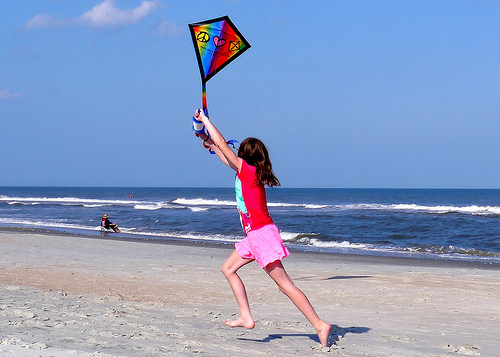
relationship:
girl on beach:
[193, 108, 338, 347] [1, 230, 499, 355]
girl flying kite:
[193, 108, 338, 347] [187, 16, 253, 115]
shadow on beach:
[238, 320, 372, 348] [1, 230, 499, 355]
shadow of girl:
[238, 320, 372, 348] [193, 108, 338, 347]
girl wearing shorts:
[193, 108, 338, 347] [233, 225, 292, 270]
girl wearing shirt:
[193, 108, 338, 347] [234, 156, 275, 234]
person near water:
[101, 213, 121, 234] [1, 186, 499, 259]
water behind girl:
[1, 186, 499, 259] [193, 108, 338, 347]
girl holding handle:
[193, 108, 338, 347] [192, 109, 205, 135]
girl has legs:
[193, 108, 338, 347] [218, 249, 332, 345]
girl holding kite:
[193, 108, 338, 347] [187, 16, 253, 115]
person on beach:
[101, 213, 121, 234] [1, 230, 499, 355]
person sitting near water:
[101, 213, 121, 234] [1, 186, 499, 259]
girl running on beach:
[193, 108, 338, 347] [1, 230, 499, 355]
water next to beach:
[1, 186, 499, 259] [1, 230, 499, 355]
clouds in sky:
[21, 2, 190, 44] [1, 1, 499, 187]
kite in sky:
[187, 16, 253, 115] [1, 1, 499, 187]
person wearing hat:
[101, 213, 121, 234] [103, 213, 111, 219]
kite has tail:
[187, 16, 253, 115] [199, 82, 240, 157]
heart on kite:
[211, 35, 226, 50] [187, 16, 253, 115]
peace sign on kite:
[195, 30, 209, 44] [187, 16, 253, 115]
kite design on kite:
[227, 38, 241, 58] [187, 16, 253, 115]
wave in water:
[3, 193, 499, 217] [1, 186, 499, 259]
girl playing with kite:
[193, 108, 338, 347] [187, 16, 253, 115]